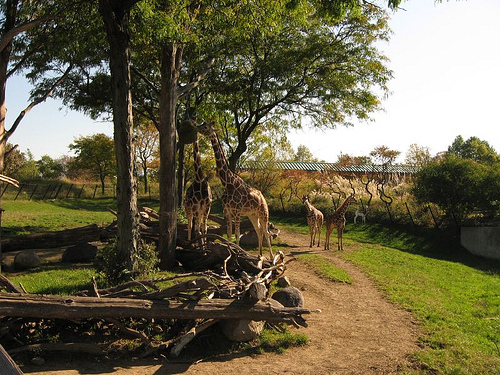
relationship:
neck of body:
[211, 134, 239, 184] [196, 121, 274, 260]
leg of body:
[259, 214, 277, 258] [196, 121, 274, 260]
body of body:
[220, 185, 270, 219] [196, 121, 274, 260]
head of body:
[196, 120, 217, 135] [196, 121, 274, 260]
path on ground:
[176, 216, 413, 373] [1, 216, 498, 375]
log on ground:
[176, 242, 279, 279] [1, 216, 498, 375]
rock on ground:
[220, 314, 269, 341] [1, 216, 498, 375]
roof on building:
[212, 162, 442, 177] [224, 160, 429, 188]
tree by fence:
[24, 4, 397, 230] [254, 195, 460, 228]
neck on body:
[211, 134, 239, 184] [196, 121, 274, 260]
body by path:
[196, 121, 274, 260] [176, 216, 413, 373]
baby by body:
[301, 193, 326, 248] [196, 121, 274, 260]